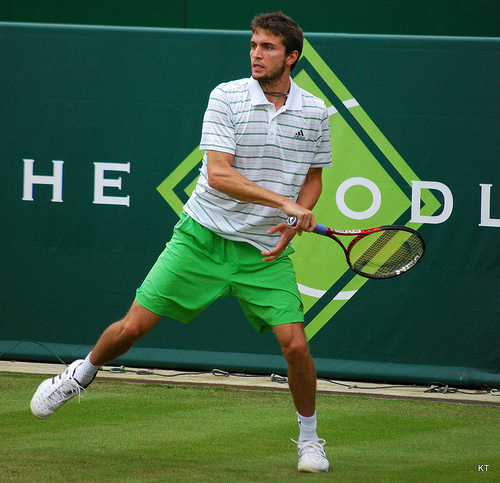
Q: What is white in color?
A: Shoe.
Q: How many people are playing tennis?
A: 1.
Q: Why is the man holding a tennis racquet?
A: To hit the ball.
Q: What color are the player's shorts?
A: Green.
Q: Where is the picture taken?
A: Tennis court.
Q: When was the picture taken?
A: During a tennis game.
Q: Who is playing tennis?
A: A man.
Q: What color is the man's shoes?
A: White.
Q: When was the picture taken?
A: During the daytime.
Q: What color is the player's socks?
A: White.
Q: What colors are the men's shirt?
A: White and green.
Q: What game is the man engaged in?
A: Tennis.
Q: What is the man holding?
A: Tennis racket.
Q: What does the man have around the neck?
A: Necklace.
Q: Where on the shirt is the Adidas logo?
A: Next to the buttons.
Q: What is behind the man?
A: A banner.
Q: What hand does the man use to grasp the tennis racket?
A: Left.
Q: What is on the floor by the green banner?
A: Cable.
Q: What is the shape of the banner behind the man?
A: Diamond.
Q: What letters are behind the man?
A: H, E, O, D, L.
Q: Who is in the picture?
A: A man.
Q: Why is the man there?
A: Tennis.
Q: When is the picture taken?
A: Day time.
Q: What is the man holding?
A: Tennis racket.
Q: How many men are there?
A: One.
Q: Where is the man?
A: On the grass.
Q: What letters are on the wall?
A: HEODL.